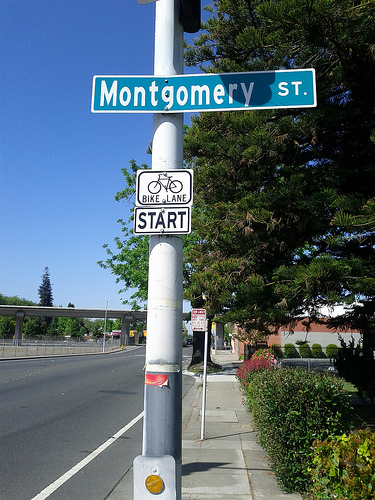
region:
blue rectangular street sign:
[86, 62, 317, 122]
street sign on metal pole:
[87, 66, 317, 114]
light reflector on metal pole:
[139, 472, 166, 497]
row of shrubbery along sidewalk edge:
[231, 349, 372, 496]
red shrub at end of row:
[233, 347, 276, 389]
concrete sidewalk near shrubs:
[174, 369, 304, 498]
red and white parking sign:
[185, 307, 209, 333]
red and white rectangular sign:
[188, 306, 208, 334]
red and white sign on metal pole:
[188, 305, 208, 336]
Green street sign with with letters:
[88, 70, 320, 111]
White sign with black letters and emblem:
[134, 167, 190, 230]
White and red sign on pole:
[190, 307, 208, 440]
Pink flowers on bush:
[249, 348, 275, 363]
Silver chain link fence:
[9, 337, 100, 356]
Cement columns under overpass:
[118, 317, 144, 348]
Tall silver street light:
[100, 295, 123, 350]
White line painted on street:
[23, 415, 132, 498]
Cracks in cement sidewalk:
[207, 399, 247, 498]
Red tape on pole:
[145, 371, 170, 389]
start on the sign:
[133, 208, 190, 234]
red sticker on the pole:
[137, 368, 175, 391]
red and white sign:
[189, 306, 207, 333]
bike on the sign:
[140, 170, 185, 196]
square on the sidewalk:
[206, 405, 238, 428]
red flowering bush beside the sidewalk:
[239, 356, 270, 372]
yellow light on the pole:
[139, 473, 167, 495]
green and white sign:
[87, 73, 315, 110]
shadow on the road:
[94, 383, 142, 400]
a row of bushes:
[244, 355, 357, 498]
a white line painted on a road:
[56, 424, 132, 497]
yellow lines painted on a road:
[23, 360, 73, 386]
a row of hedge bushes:
[278, 342, 339, 357]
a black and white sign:
[125, 161, 204, 237]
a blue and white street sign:
[64, 70, 312, 117]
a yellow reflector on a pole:
[138, 466, 174, 499]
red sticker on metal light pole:
[136, 353, 194, 414]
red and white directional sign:
[186, 301, 209, 338]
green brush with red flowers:
[231, 339, 282, 397]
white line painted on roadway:
[20, 407, 138, 499]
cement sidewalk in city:
[185, 365, 306, 497]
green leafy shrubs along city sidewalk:
[252, 364, 373, 486]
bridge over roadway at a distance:
[2, 289, 155, 367]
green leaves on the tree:
[228, 149, 273, 205]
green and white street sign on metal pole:
[85, 66, 320, 115]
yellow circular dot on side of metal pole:
[141, 472, 167, 497]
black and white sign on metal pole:
[131, 205, 193, 237]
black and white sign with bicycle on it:
[133, 166, 195, 205]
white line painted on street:
[29, 411, 143, 498]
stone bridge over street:
[0, 301, 193, 328]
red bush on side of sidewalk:
[232, 354, 280, 388]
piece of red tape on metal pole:
[142, 370, 170, 388]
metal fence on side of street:
[0, 335, 121, 360]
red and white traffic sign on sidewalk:
[186, 306, 209, 333]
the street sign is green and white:
[90, 66, 316, 111]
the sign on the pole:
[191, 307, 208, 439]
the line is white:
[30, 408, 144, 499]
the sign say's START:
[132, 206, 190, 233]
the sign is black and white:
[133, 205, 191, 234]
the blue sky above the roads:
[0, 0, 373, 498]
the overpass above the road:
[0, 304, 235, 496]